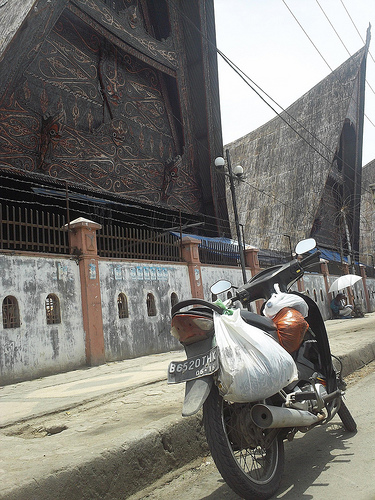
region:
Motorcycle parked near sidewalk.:
[165, 236, 357, 499]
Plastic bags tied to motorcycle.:
[165, 235, 359, 498]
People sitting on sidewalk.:
[327, 272, 366, 319]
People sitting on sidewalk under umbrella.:
[326, 272, 366, 320]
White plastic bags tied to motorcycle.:
[163, 235, 359, 498]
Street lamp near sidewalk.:
[212, 145, 246, 278]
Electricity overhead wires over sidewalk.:
[161, 0, 373, 193]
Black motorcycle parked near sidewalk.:
[165, 236, 357, 499]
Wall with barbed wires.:
[0, 172, 374, 390]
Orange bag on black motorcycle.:
[163, 236, 358, 498]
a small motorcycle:
[159, 234, 367, 494]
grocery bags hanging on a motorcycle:
[198, 289, 320, 409]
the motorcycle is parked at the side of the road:
[167, 235, 358, 498]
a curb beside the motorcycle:
[6, 301, 373, 496]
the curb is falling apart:
[13, 379, 176, 459]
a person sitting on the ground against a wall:
[330, 264, 369, 325]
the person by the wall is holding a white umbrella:
[327, 264, 365, 324]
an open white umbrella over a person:
[322, 264, 364, 320]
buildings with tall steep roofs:
[2, 2, 373, 285]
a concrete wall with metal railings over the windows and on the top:
[0, 216, 373, 372]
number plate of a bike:
[169, 360, 224, 375]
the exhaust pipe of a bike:
[248, 403, 275, 427]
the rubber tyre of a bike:
[208, 414, 226, 468]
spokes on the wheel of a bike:
[241, 445, 259, 468]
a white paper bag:
[219, 318, 282, 391]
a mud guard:
[180, 381, 205, 417]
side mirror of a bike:
[297, 238, 314, 255]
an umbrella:
[335, 271, 361, 291]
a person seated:
[332, 293, 353, 314]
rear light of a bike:
[188, 318, 215, 328]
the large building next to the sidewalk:
[0, 0, 373, 386]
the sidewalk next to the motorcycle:
[0, 309, 373, 497]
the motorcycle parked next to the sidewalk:
[167, 236, 356, 497]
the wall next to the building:
[0, 202, 374, 385]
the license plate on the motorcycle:
[167, 346, 218, 383]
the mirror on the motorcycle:
[295, 238, 315, 255]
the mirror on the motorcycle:
[210, 279, 231, 294]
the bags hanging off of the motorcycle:
[210, 281, 308, 402]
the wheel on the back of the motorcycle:
[202, 378, 283, 497]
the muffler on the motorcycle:
[250, 402, 319, 427]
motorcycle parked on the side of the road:
[153, 240, 362, 497]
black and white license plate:
[161, 348, 227, 387]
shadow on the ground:
[187, 414, 357, 499]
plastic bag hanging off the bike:
[206, 307, 300, 406]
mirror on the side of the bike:
[208, 273, 234, 297]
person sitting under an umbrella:
[327, 267, 367, 326]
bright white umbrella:
[327, 270, 364, 291]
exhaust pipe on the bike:
[245, 404, 329, 430]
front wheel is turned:
[327, 378, 367, 436]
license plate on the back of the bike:
[159, 350, 230, 382]